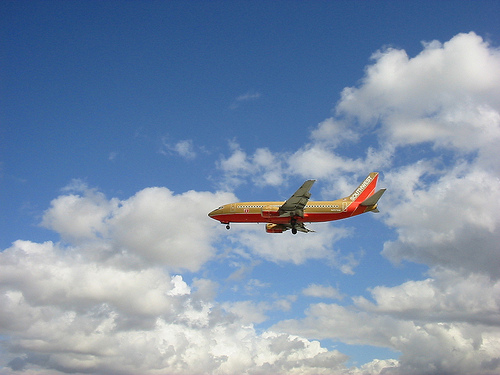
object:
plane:
[208, 170, 389, 237]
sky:
[4, 2, 500, 371]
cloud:
[331, 32, 499, 159]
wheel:
[291, 228, 297, 234]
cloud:
[113, 184, 239, 265]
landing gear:
[283, 208, 307, 222]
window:
[239, 205, 243, 209]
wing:
[276, 179, 316, 216]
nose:
[208, 208, 218, 221]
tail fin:
[344, 172, 386, 213]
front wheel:
[226, 225, 230, 229]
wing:
[279, 215, 316, 233]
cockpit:
[217, 204, 224, 211]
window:
[330, 204, 334, 207]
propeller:
[277, 194, 313, 210]